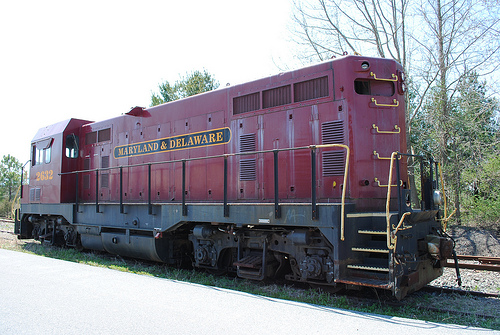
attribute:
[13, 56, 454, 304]
train — black, here, red, parked, large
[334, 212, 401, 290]
staircase — here, black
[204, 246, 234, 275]
wheel — metallic, black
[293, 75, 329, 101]
window — here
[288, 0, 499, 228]
tree — large, green, tall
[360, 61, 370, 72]
light — off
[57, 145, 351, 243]
rail — yellow, black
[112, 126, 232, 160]
logo — yellow, black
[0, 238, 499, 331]
grass — green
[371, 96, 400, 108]
rung — yellow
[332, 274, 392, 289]
step — black, yellow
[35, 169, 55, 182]
logo — yellow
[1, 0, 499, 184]
sky — light